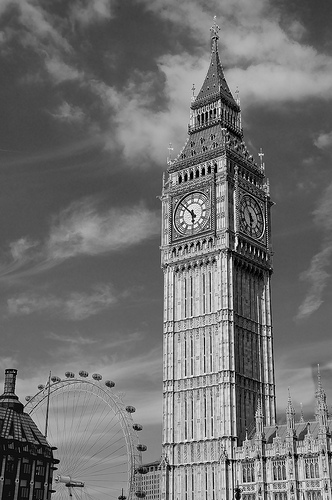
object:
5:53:
[172, 190, 211, 238]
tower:
[156, 14, 278, 499]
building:
[155, 14, 331, 499]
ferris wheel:
[22, 370, 148, 499]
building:
[0, 368, 60, 500]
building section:
[234, 363, 331, 499]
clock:
[170, 188, 210, 236]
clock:
[238, 190, 265, 242]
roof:
[167, 14, 266, 175]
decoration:
[166, 141, 175, 165]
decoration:
[257, 146, 265, 171]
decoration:
[190, 82, 196, 100]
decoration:
[234, 83, 239, 103]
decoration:
[208, 14, 222, 39]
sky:
[0, 1, 331, 500]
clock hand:
[179, 202, 197, 218]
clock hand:
[190, 209, 195, 236]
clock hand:
[244, 197, 254, 222]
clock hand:
[248, 214, 253, 235]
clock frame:
[168, 181, 216, 247]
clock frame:
[238, 186, 268, 247]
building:
[130, 460, 161, 498]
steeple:
[253, 390, 264, 433]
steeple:
[285, 386, 297, 428]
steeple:
[313, 363, 329, 432]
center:
[54, 473, 72, 484]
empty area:
[23, 378, 140, 466]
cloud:
[291, 187, 330, 326]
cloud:
[0, 280, 151, 324]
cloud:
[291, 244, 331, 323]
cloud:
[308, 129, 330, 150]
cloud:
[0, 0, 331, 417]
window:
[242, 467, 247, 483]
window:
[246, 467, 251, 484]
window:
[250, 467, 255, 482]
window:
[273, 465, 278, 480]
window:
[277, 464, 282, 480]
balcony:
[189, 101, 219, 129]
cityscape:
[0, 0, 331, 499]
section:
[155, 150, 276, 271]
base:
[159, 256, 277, 500]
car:
[105, 378, 115, 388]